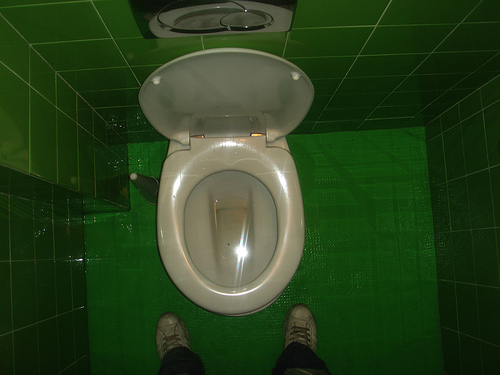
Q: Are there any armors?
A: No, there are no armors.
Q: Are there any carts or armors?
A: No, there are no armors or carts.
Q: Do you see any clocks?
A: No, there are no clocks.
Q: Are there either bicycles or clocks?
A: No, there are no clocks or bicycles.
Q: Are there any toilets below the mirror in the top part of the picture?
A: Yes, there is a toilet below the mirror.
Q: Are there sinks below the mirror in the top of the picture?
A: No, there is a toilet below the mirror.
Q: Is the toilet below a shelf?
A: No, the toilet is below a mirror.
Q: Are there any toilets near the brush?
A: Yes, there is a toilet near the brush.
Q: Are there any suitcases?
A: No, there are no suitcases.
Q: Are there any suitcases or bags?
A: No, there are no suitcases or bags.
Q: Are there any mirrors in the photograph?
A: Yes, there is a mirror.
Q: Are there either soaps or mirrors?
A: Yes, there is a mirror.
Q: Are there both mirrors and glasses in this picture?
A: No, there is a mirror but no glasses.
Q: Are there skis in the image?
A: No, there are no skis.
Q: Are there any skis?
A: No, there are no skis.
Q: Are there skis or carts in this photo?
A: No, there are no skis or carts.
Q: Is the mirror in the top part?
A: Yes, the mirror is in the top of the image.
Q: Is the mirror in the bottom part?
A: No, the mirror is in the top of the image.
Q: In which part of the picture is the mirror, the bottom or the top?
A: The mirror is in the top of the image.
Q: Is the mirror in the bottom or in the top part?
A: The mirror is in the top of the image.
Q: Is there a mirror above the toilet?
A: Yes, there is a mirror above the toilet.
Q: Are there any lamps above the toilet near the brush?
A: No, there is a mirror above the toilet.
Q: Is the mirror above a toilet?
A: Yes, the mirror is above a toilet.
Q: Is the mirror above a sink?
A: No, the mirror is above a toilet.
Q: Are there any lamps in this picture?
A: No, there are no lamps.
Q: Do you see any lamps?
A: No, there are no lamps.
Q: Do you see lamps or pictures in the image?
A: No, there are no lamps or pictures.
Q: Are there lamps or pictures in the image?
A: No, there are no lamps or pictures.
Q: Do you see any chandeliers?
A: No, there are no chandeliers.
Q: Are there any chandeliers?
A: No, there are no chandeliers.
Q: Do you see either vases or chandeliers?
A: No, there are no chandeliers or vases.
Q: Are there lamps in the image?
A: No, there are no lamps.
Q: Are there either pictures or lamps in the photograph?
A: No, there are no lamps or pictures.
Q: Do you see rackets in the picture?
A: No, there are no rackets.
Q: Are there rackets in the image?
A: No, there are no rackets.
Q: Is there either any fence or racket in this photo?
A: No, there are no rackets or fences.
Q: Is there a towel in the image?
A: No, there are no towels.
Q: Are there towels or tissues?
A: No, there are no towels or tissues.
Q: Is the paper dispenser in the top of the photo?
A: Yes, the paper dispenser is in the top of the image.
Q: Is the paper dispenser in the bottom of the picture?
A: No, the paper dispenser is in the top of the image.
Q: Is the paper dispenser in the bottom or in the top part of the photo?
A: The paper dispenser is in the top of the image.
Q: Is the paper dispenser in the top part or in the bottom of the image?
A: The paper dispenser is in the top of the image.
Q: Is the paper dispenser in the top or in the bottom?
A: The paper dispenser is in the top of the image.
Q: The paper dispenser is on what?
A: The paper dispenser is on the wall.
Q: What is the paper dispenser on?
A: The paper dispenser is on the wall.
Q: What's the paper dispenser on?
A: The paper dispenser is on the wall.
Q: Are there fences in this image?
A: No, there are no fences.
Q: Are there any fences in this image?
A: No, there are no fences.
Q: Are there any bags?
A: No, there are no bags.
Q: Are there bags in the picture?
A: No, there are no bags.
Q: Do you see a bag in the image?
A: No, there are no bags.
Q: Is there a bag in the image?
A: No, there are no bags.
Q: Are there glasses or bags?
A: No, there are no bags or glasses.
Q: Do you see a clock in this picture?
A: No, there are no clocks.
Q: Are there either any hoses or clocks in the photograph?
A: No, there are no clocks or hoses.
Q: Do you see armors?
A: No, there are no armors.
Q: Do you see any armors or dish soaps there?
A: No, there are no armors or dish soaps.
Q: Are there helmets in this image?
A: No, there are no helmets.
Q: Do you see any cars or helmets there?
A: No, there are no helmets or cars.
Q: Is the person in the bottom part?
A: Yes, the person is in the bottom of the image.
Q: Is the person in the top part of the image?
A: No, the person is in the bottom of the image.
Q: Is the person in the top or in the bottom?
A: The person is in the bottom of the image.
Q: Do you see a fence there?
A: No, there are no fences.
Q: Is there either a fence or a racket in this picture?
A: No, there are no fences or rackets.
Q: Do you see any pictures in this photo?
A: No, there are no pictures.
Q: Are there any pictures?
A: No, there are no pictures.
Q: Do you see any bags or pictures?
A: No, there are no pictures or bags.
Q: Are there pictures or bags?
A: No, there are no pictures or bags.